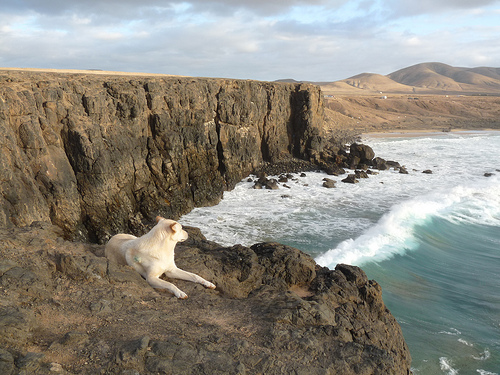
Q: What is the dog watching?
A: Waves.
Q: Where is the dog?
A: Sitting on the ground.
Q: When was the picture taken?
A: Daytime.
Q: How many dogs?
A: One.